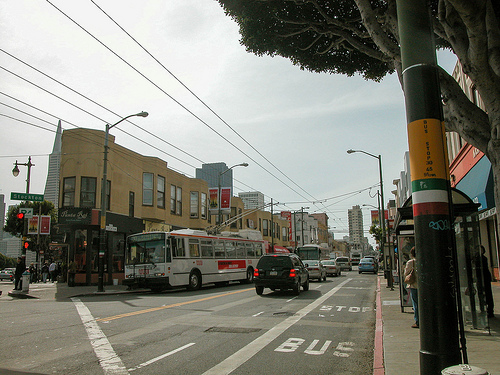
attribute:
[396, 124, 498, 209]
patch — yellow, square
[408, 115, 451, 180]
patch — yellow, square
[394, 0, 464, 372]
pole — yellow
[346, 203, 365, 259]
building — tall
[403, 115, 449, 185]
patch — square, yellow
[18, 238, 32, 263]
walk light — pedestrian, lit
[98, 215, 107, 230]
yellow patch — square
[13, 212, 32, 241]
traffic light — red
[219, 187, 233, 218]
patch — square, yellow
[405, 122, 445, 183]
square patch — yellow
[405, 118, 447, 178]
yellow patch — square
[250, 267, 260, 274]
light — brake light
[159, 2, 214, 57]
cloud — part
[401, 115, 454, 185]
patch — square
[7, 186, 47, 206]
street sign — green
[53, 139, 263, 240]
building — beige